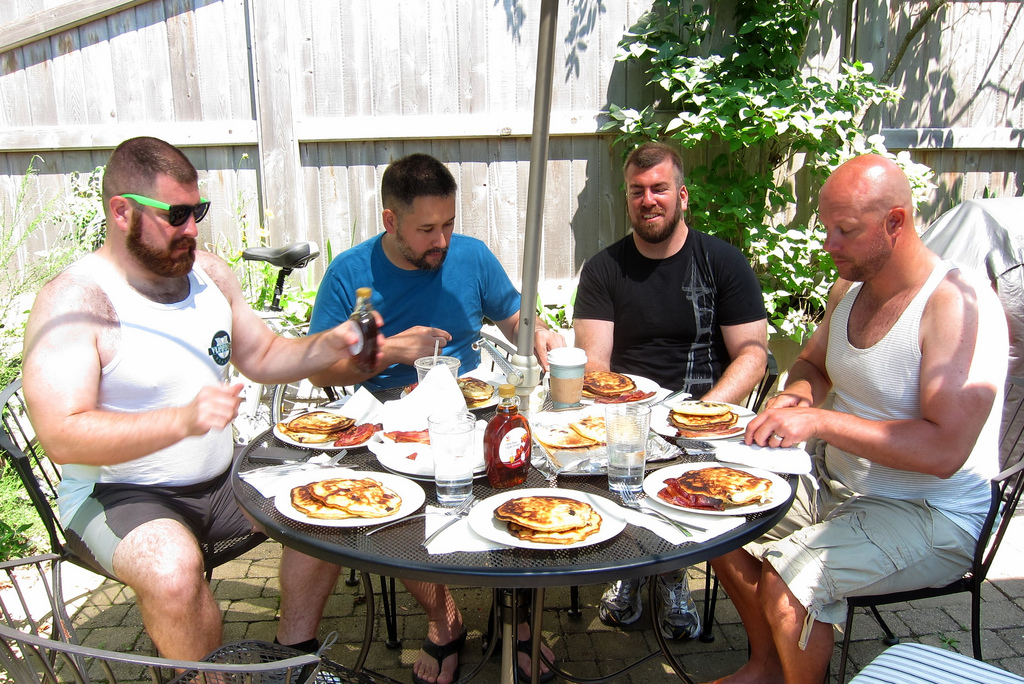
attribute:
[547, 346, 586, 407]
cup — blue , white 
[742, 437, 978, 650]
shorts — tan 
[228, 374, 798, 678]
table — black 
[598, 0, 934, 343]
tree — green 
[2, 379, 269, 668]
chair — black 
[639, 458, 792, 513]
plate — white 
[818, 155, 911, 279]
head — bald 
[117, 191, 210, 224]
sunglasses — black , green 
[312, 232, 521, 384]
shirt — blue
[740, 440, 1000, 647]
shorts — beige, man's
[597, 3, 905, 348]
tree — tall, green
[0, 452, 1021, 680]
patio — brick, paved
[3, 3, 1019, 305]
fence — wooden 